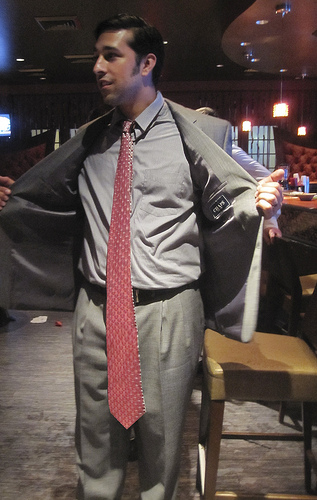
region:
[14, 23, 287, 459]
a man with a super long tie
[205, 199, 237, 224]
a designer label inside the man's jacket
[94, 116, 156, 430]
a super long tie the man is wearing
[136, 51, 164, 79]
the ear on the man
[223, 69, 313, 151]
hanging lamps in the back of the room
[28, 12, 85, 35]
an air vent in the ceiling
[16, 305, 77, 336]
trash on the floor of the establishement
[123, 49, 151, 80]
a sideburn on the man's face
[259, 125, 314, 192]
a padded seat back on a booth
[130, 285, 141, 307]
a gold belt buckle on the man's belt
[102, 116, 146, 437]
Red tie with spots.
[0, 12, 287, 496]
Person wearing a red tie.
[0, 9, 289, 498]
Person wearing gray pants.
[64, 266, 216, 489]
Pair of gray pants.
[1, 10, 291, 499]
Person wearing a gray coat.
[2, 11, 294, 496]
Person wearing a belt.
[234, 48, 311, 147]
Three lights hanging from the ceiling.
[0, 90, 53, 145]
TV turned on next to a window.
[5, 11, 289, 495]
Person wearing a collared shirt.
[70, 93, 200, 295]
Gray collared shirt with buttons.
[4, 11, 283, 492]
a man in a grey suit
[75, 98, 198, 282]
a grey shirt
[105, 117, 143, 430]
a very long red tie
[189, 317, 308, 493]
a yellow padded stool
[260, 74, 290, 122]
overhead hanging lights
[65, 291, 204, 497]
grey pleated men's pants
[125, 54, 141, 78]
a man's sideburn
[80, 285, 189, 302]
a black belt and buckle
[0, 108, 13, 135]
a TV screen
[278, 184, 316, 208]
dishes on a countertop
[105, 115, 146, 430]
A red designed tie.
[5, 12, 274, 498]
A man in a gray suit.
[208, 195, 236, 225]
Label inside man's jacket.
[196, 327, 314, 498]
A brown bar stool.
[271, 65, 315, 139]
Lights hanging from ceiling.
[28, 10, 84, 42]
A vent in ceiling.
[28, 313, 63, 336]
Trash on the floor.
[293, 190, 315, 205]
Bowl sitting on bar counter.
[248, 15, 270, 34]
Light embedded in ceiling.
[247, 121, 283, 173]
Window in wall of bar.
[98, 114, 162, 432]
a long, pink tie.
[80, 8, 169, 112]
a man's head with brown hair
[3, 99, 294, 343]
a man's grey shirt and jacket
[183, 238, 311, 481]
an empty beige bar stool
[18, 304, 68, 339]
two pieces of debris on the floor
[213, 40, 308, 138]
three hanging pendant lights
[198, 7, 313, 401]
an empty bar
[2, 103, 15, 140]
the edge of a television monitor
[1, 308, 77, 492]
a littered and dirty floor